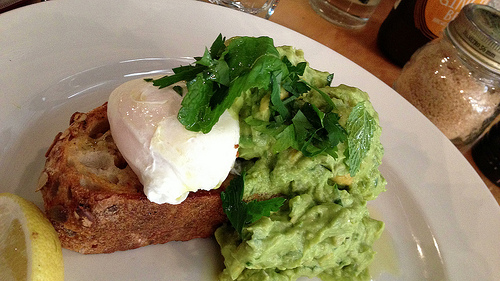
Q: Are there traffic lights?
A: No, there are no traffic lights.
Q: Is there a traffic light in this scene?
A: No, there are no traffic lights.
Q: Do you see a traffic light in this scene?
A: No, there are no traffic lights.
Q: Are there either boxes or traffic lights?
A: No, there are no traffic lights or boxes.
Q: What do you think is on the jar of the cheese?
A: The lid is on the jar.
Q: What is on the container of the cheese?
A: The lid is on the jar.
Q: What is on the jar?
A: The lid is on the jar.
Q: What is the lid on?
A: The lid is on the jar.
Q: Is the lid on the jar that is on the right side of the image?
A: Yes, the lid is on the jar.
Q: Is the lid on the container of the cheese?
A: Yes, the lid is on the jar.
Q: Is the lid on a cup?
A: No, the lid is on the jar.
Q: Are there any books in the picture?
A: No, there are no books.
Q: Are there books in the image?
A: No, there are no books.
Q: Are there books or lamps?
A: No, there are no books or lamps.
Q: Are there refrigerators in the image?
A: No, there are no refrigerators.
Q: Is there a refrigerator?
A: No, there are no refrigerators.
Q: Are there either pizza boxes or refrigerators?
A: No, there are no refrigerators or pizza boxes.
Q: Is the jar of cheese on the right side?
A: Yes, the jar is on the right of the image.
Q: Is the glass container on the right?
A: Yes, the jar is on the right of the image.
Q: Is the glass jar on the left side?
A: No, the jar is on the right of the image.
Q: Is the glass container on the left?
A: No, the jar is on the right of the image.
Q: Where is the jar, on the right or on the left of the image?
A: The jar is on the right of the image.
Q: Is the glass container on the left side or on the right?
A: The jar is on the right of the image.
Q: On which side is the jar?
A: The jar is on the right of the image.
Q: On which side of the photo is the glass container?
A: The jar is on the right of the image.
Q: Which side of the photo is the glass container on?
A: The jar is on the right of the image.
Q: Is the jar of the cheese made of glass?
A: Yes, the jar is made of glass.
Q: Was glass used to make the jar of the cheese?
A: Yes, the jar is made of glass.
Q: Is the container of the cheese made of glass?
A: Yes, the jar is made of glass.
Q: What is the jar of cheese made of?
A: The jar is made of glass.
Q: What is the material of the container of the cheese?
A: The jar is made of glass.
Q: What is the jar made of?
A: The jar is made of glass.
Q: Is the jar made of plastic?
A: No, the jar is made of glass.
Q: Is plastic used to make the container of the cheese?
A: No, the jar is made of glass.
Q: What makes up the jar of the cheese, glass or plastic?
A: The jar is made of glass.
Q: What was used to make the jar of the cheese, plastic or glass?
A: The jar is made of glass.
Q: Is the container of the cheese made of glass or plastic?
A: The jar is made of glass.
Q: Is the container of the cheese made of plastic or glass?
A: The jar is made of glass.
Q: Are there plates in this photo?
A: Yes, there is a plate.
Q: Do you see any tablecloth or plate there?
A: Yes, there is a plate.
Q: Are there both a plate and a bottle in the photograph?
A: Yes, there are both a plate and a bottle.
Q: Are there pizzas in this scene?
A: No, there are no pizzas.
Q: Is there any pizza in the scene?
A: No, there are no pizzas.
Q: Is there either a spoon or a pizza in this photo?
A: No, there are no pizzas or spoons.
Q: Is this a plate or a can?
A: This is a plate.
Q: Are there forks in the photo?
A: No, there are no forks.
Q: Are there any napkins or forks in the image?
A: No, there are no forks or napkins.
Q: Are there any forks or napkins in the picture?
A: No, there are no forks or napkins.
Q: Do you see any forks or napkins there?
A: No, there are no forks or napkins.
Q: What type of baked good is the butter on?
A: The butter is on the bread.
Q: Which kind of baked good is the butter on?
A: The butter is on the bread.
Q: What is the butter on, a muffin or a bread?
A: The butter is on a bread.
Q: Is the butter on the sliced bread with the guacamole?
A: Yes, the butter is on the bread.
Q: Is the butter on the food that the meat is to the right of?
A: Yes, the butter is on the bread.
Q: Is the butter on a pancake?
A: No, the butter is on the bread.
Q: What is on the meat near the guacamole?
A: The butter is on the meat.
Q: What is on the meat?
A: The butter is on the meat.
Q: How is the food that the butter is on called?
A: The food is meat.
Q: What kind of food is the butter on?
A: The butter is on the meat.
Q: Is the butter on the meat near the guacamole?
A: Yes, the butter is on the meat.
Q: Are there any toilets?
A: No, there are no toilets.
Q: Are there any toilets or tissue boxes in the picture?
A: No, there are no toilets or tissue boxes.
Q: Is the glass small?
A: Yes, the glass is small.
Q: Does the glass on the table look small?
A: Yes, the glass is small.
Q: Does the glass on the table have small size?
A: Yes, the glass is small.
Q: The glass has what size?
A: The glass is small.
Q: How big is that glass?
A: The glass is small.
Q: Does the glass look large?
A: No, the glass is small.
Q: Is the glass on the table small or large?
A: The glass is small.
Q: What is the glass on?
A: The glass is on the table.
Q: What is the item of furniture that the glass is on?
A: The piece of furniture is a table.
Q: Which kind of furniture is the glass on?
A: The glass is on the table.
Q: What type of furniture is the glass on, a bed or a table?
A: The glass is on a table.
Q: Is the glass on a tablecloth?
A: No, the glass is on the table.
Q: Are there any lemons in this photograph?
A: Yes, there is a lemon.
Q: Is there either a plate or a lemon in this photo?
A: Yes, there is a lemon.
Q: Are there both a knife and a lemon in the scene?
A: No, there is a lemon but no knives.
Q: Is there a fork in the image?
A: No, there are no forks.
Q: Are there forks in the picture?
A: No, there are no forks.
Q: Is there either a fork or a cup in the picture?
A: No, there are no forks or cups.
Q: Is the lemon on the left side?
A: Yes, the lemon is on the left of the image.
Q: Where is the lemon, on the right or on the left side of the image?
A: The lemon is on the left of the image.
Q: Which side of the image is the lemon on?
A: The lemon is on the left of the image.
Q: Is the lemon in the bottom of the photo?
A: Yes, the lemon is in the bottom of the image.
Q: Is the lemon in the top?
A: No, the lemon is in the bottom of the image.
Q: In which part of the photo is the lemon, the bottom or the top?
A: The lemon is in the bottom of the image.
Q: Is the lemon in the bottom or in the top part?
A: The lemon is in the bottom of the image.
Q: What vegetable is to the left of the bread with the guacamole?
A: The vegetable is a lemon.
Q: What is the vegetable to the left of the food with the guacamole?
A: The vegetable is a lemon.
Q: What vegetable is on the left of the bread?
A: The vegetable is a lemon.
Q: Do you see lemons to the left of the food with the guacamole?
A: Yes, there is a lemon to the left of the bread.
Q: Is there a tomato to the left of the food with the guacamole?
A: No, there is a lemon to the left of the bread.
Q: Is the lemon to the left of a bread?
A: Yes, the lemon is to the left of a bread.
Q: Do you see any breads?
A: Yes, there is a bread.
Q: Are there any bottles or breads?
A: Yes, there is a bread.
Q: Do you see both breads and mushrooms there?
A: No, there is a bread but no mushrooms.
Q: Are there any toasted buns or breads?
A: Yes, there is a toasted bread.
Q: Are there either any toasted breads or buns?
A: Yes, there is a toasted bread.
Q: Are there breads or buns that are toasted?
A: Yes, the bread is toasted.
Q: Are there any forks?
A: No, there are no forks.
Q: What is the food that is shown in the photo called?
A: The food is a bread.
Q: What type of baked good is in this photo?
A: The baked good is a bread.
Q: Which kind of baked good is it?
A: The food is a bread.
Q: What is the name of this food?
A: This is a bread.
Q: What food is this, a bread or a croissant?
A: This is a bread.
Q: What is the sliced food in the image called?
A: The food is a bread.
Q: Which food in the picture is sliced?
A: The food is a bread.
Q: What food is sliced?
A: The food is a bread.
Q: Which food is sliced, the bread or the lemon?
A: The bread is sliced.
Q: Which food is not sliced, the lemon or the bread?
A: The lemon is not sliced.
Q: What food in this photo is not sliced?
A: The food is a lemon.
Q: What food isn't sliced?
A: The food is a lemon.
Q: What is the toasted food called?
A: The food is a bread.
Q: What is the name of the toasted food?
A: The food is a bread.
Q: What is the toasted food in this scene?
A: The food is a bread.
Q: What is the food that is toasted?
A: The food is a bread.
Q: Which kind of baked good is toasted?
A: The baked good is a bread.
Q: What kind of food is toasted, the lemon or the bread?
A: The bread is toasted.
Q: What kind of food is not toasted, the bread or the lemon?
A: The lemon is not toasted.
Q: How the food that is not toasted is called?
A: The food is a lemon.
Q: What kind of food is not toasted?
A: The food is a lemon.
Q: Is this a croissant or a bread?
A: This is a bread.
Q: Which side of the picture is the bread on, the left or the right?
A: The bread is on the left of the image.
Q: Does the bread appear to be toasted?
A: Yes, the bread is toasted.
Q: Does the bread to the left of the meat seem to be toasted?
A: Yes, the bread is toasted.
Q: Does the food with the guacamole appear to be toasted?
A: Yes, the bread is toasted.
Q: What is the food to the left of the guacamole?
A: The food is a bread.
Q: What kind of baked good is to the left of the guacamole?
A: The food is a bread.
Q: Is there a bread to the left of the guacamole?
A: Yes, there is a bread to the left of the guacamole.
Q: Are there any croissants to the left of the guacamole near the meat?
A: No, there is a bread to the left of the guacamole.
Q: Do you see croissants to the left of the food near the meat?
A: No, there is a bread to the left of the guacamole.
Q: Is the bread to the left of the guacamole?
A: Yes, the bread is to the left of the guacamole.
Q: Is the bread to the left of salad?
A: No, the bread is to the left of the guacamole.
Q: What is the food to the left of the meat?
A: The food is a bread.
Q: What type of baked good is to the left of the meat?
A: The food is a bread.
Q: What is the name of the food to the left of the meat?
A: The food is a bread.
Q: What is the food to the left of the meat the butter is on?
A: The food is a bread.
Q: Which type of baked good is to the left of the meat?
A: The food is a bread.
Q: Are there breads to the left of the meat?
A: Yes, there is a bread to the left of the meat.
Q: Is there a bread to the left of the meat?
A: Yes, there is a bread to the left of the meat.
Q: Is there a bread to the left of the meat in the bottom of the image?
A: Yes, there is a bread to the left of the meat.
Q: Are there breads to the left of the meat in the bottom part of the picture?
A: Yes, there is a bread to the left of the meat.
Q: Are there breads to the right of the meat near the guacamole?
A: No, the bread is to the left of the meat.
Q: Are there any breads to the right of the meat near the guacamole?
A: No, the bread is to the left of the meat.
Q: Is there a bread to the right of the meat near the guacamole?
A: No, the bread is to the left of the meat.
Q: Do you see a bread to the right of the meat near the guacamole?
A: No, the bread is to the left of the meat.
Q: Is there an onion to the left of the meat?
A: No, there is a bread to the left of the meat.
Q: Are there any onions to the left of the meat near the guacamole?
A: No, there is a bread to the left of the meat.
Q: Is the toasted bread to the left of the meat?
A: Yes, the bread is to the left of the meat.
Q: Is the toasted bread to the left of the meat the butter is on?
A: Yes, the bread is to the left of the meat.